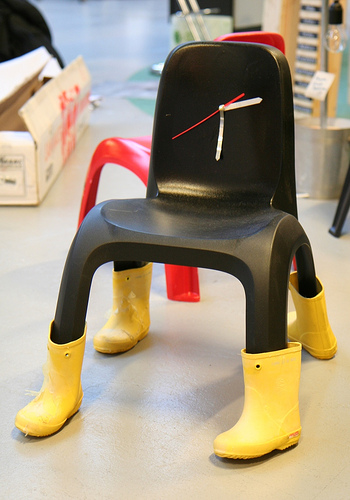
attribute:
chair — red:
[78, 31, 295, 301]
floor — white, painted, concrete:
[5, 4, 345, 497]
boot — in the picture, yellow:
[212, 338, 302, 459]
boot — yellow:
[94, 260, 153, 354]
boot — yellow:
[12, 316, 87, 437]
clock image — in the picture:
[166, 64, 276, 172]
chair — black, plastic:
[13, 35, 339, 463]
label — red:
[41, 85, 89, 162]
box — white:
[0, 45, 89, 205]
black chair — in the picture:
[50, 38, 322, 354]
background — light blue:
[60, 8, 212, 112]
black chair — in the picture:
[11, 34, 324, 460]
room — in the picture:
[2, 2, 347, 499]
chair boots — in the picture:
[9, 46, 317, 450]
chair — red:
[65, 71, 325, 308]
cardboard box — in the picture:
[3, 57, 98, 210]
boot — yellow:
[11, 317, 96, 437]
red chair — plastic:
[67, 32, 288, 301]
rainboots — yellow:
[290, 271, 343, 358]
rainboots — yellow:
[98, 270, 153, 358]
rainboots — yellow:
[211, 345, 301, 460]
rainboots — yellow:
[9, 318, 87, 438]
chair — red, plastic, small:
[53, 40, 316, 351]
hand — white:
[218, 99, 269, 112]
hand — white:
[210, 119, 225, 166]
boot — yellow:
[285, 270, 339, 362]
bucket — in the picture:
[292, 114, 349, 203]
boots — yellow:
[11, 263, 336, 461]